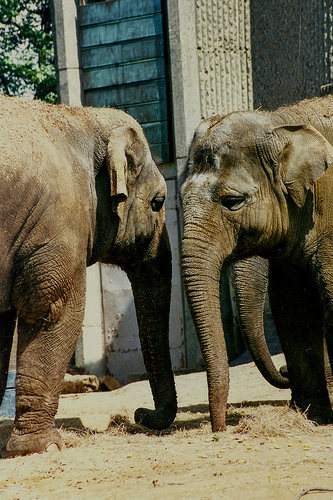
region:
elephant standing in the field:
[159, 98, 331, 435]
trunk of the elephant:
[148, 220, 259, 447]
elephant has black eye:
[214, 180, 259, 224]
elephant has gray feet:
[16, 402, 69, 470]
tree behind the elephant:
[2, 1, 85, 108]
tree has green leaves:
[4, 9, 75, 121]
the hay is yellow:
[146, 425, 286, 488]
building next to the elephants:
[49, 2, 300, 472]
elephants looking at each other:
[4, 76, 311, 490]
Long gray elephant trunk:
[181, 218, 230, 428]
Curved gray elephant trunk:
[226, 251, 287, 384]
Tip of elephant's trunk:
[131, 406, 145, 423]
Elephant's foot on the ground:
[5, 426, 69, 453]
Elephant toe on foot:
[44, 441, 57, 450]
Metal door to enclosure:
[105, 265, 155, 382]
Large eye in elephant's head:
[219, 191, 251, 209]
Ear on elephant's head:
[272, 119, 331, 207]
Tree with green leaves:
[2, 2, 64, 105]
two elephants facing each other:
[50, 91, 279, 462]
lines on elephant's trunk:
[168, 190, 226, 426]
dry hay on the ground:
[79, 396, 303, 457]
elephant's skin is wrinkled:
[26, 250, 81, 387]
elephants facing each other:
[0, 65, 328, 414]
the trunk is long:
[116, 216, 189, 423]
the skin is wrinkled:
[181, 184, 229, 371]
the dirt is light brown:
[97, 429, 279, 487]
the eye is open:
[203, 182, 259, 218]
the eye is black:
[206, 185, 258, 219]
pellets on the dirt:
[212, 425, 310, 459]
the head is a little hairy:
[170, 92, 287, 172]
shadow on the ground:
[161, 380, 284, 423]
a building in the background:
[40, 3, 271, 108]